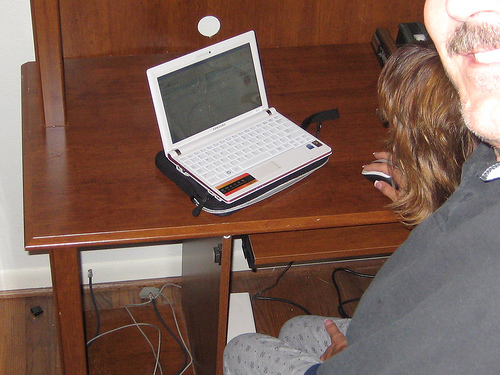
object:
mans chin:
[456, 85, 500, 145]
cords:
[84, 268, 101, 349]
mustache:
[445, 22, 500, 56]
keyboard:
[178, 113, 312, 187]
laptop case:
[152, 148, 333, 216]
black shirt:
[312, 140, 500, 374]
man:
[311, 0, 500, 375]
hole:
[197, 16, 222, 38]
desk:
[20, 43, 455, 375]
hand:
[361, 151, 412, 201]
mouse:
[361, 158, 401, 191]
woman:
[219, 44, 479, 375]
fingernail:
[373, 179, 382, 191]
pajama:
[222, 314, 352, 375]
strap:
[301, 107, 340, 129]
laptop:
[145, 29, 333, 205]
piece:
[28, 305, 43, 318]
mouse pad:
[248, 157, 281, 183]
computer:
[145, 29, 333, 206]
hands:
[317, 318, 350, 363]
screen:
[156, 42, 261, 142]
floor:
[0, 254, 395, 375]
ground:
[0, 259, 391, 375]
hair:
[374, 42, 483, 228]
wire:
[84, 322, 163, 375]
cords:
[249, 260, 315, 317]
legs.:
[277, 313, 351, 359]